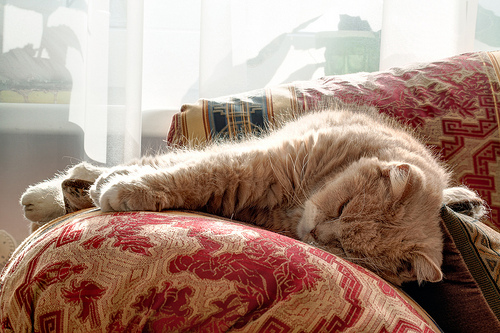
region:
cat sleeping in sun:
[69, 120, 454, 262]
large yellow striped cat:
[78, 140, 459, 248]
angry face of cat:
[300, 162, 379, 275]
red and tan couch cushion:
[55, 213, 323, 301]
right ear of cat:
[362, 149, 425, 208]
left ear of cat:
[402, 236, 447, 294]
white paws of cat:
[18, 156, 166, 238]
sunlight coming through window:
[59, 8, 256, 145]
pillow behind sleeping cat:
[427, 172, 494, 307]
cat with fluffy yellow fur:
[180, 141, 418, 246]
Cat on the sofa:
[8, 100, 493, 285]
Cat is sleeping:
[20, 117, 468, 289]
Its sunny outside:
[22, 15, 463, 155]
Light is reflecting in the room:
[27, 8, 436, 143]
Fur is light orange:
[76, 108, 467, 290]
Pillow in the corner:
[366, 112, 499, 292]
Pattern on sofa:
[11, 200, 456, 327]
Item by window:
[5, 25, 132, 106]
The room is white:
[9, 47, 183, 169]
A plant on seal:
[310, 9, 395, 74]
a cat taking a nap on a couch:
[26, 107, 458, 287]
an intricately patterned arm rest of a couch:
[29, 222, 320, 327]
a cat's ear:
[388, 161, 418, 203]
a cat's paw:
[18, 183, 59, 214]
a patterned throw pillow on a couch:
[444, 205, 496, 326]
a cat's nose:
[310, 226, 326, 241]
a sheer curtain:
[70, 2, 137, 162]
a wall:
[18, 136, 53, 161]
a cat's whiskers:
[275, 156, 311, 201]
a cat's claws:
[109, 200, 163, 214]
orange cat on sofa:
[150, 106, 442, 247]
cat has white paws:
[85, 163, 152, 214]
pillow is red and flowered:
[47, 202, 349, 329]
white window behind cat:
[25, 23, 248, 112]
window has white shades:
[14, 30, 181, 179]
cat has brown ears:
[373, 157, 430, 289]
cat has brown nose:
[304, 202, 341, 247]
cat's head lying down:
[297, 120, 479, 298]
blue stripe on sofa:
[176, 91, 351, 199]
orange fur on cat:
[195, 112, 325, 224]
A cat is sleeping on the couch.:
[56, 129, 458, 280]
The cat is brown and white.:
[138, 138, 413, 245]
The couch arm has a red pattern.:
[76, 218, 300, 320]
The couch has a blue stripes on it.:
[172, 84, 312, 135]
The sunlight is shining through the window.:
[66, 15, 288, 80]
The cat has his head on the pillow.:
[422, 176, 497, 308]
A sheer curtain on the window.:
[49, 29, 276, 104]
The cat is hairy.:
[197, 116, 341, 188]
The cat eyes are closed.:
[317, 166, 352, 254]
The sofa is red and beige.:
[65, 219, 310, 300]